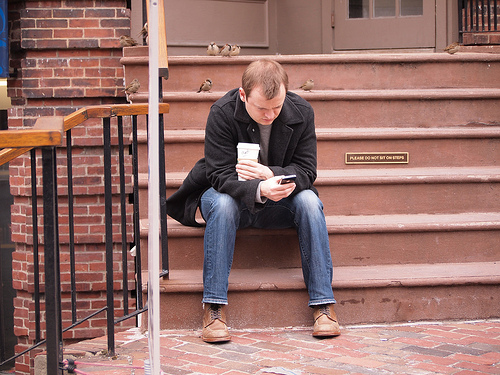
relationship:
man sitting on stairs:
[166, 59, 344, 343] [122, 51, 498, 329]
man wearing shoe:
[166, 59, 344, 343] [201, 301, 229, 342]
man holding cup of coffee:
[166, 59, 344, 343] [234, 141, 260, 182]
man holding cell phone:
[166, 59, 344, 343] [278, 174, 297, 190]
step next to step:
[122, 49, 498, 91] [134, 94, 498, 136]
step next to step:
[133, 131, 499, 177] [135, 175, 500, 219]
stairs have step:
[122, 51, 498, 329] [138, 218, 499, 269]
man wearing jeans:
[166, 59, 344, 343] [198, 186, 339, 307]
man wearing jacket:
[166, 59, 344, 343] [167, 90, 318, 224]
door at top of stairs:
[325, 1, 445, 54] [122, 51, 498, 329]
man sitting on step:
[166, 59, 344, 343] [135, 175, 500, 219]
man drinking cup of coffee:
[166, 59, 344, 343] [234, 141, 260, 182]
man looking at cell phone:
[166, 59, 344, 343] [278, 174, 297, 190]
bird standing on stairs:
[205, 39, 221, 57] [122, 51, 498, 329]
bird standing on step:
[126, 77, 142, 95] [122, 49, 498, 91]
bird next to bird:
[197, 79, 215, 95] [299, 79, 319, 93]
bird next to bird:
[222, 41, 237, 56] [205, 39, 221, 57]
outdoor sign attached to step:
[344, 149, 413, 165] [133, 131, 499, 177]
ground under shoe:
[33, 321, 498, 374] [201, 301, 229, 342]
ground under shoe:
[33, 321, 498, 374] [312, 303, 337, 336]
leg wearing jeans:
[201, 190, 246, 306] [198, 186, 339, 307]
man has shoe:
[166, 59, 344, 343] [201, 301, 229, 342]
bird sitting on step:
[126, 77, 142, 95] [122, 49, 498, 91]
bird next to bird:
[205, 39, 221, 57] [222, 41, 237, 56]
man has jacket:
[166, 59, 344, 343] [167, 90, 318, 224]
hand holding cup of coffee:
[235, 163, 274, 184] [234, 141, 260, 182]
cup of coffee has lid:
[234, 141, 260, 182] [235, 143, 262, 151]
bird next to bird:
[299, 79, 319, 93] [197, 79, 215, 95]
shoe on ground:
[201, 301, 229, 342] [33, 321, 498, 374]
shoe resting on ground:
[312, 303, 337, 336] [33, 321, 498, 374]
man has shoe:
[166, 59, 344, 343] [312, 303, 337, 336]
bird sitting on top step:
[205, 39, 221, 57] [125, 47, 499, 66]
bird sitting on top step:
[222, 41, 237, 56] [125, 47, 499, 66]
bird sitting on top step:
[234, 45, 244, 58] [125, 47, 499, 66]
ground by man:
[33, 321, 498, 374] [166, 59, 344, 343]